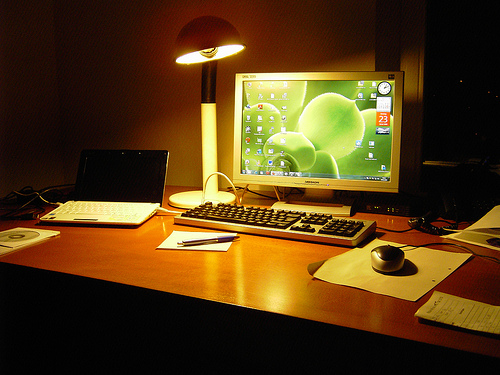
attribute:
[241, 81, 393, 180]
desktop — green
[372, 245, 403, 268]
mouse — black, silver, grey, white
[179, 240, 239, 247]
pen — blue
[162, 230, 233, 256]
notebook — white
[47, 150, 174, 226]
laptop — black, white, silver, small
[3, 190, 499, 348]
desk — brown, wooden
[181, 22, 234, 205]
lamp — metal, on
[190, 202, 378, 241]
keyboard — grey, black, silver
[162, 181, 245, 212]
wire — black, white